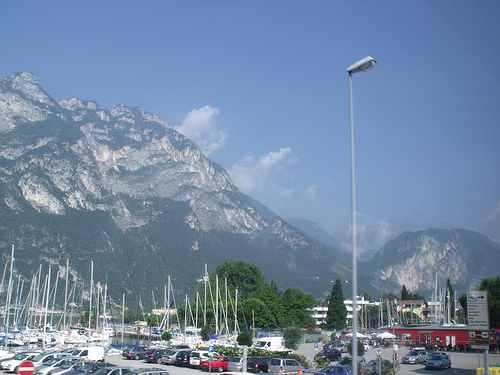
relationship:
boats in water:
[4, 244, 112, 344] [112, 330, 151, 352]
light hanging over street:
[292, 50, 417, 375] [243, 331, 463, 375]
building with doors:
[383, 324, 483, 349] [444, 331, 454, 346]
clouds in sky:
[164, 94, 328, 163] [199, 97, 397, 198]